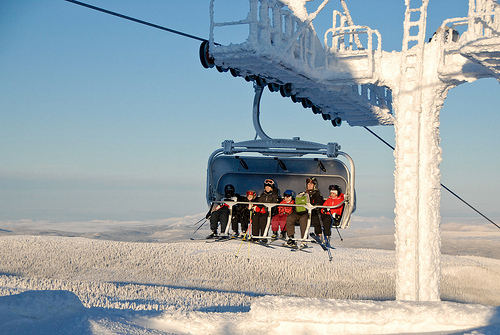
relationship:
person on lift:
[284, 174, 321, 251] [206, 135, 356, 232]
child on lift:
[235, 191, 256, 233] [206, 135, 356, 232]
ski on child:
[232, 231, 275, 249] [235, 191, 256, 233]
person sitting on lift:
[284, 174, 321, 251] [206, 135, 356, 232]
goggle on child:
[245, 189, 258, 196] [235, 191, 256, 233]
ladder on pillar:
[394, 2, 430, 306] [387, 81, 448, 303]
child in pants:
[235, 191, 256, 233] [269, 215, 289, 235]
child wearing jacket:
[235, 191, 256, 233] [316, 193, 345, 215]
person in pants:
[284, 174, 321, 251] [269, 215, 289, 235]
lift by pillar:
[206, 135, 356, 232] [387, 81, 448, 303]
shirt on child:
[215, 194, 237, 209] [235, 191, 256, 233]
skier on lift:
[285, 172, 319, 248] [206, 135, 356, 232]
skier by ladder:
[285, 172, 319, 248] [394, 2, 430, 306]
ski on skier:
[232, 231, 275, 249] [285, 172, 319, 248]